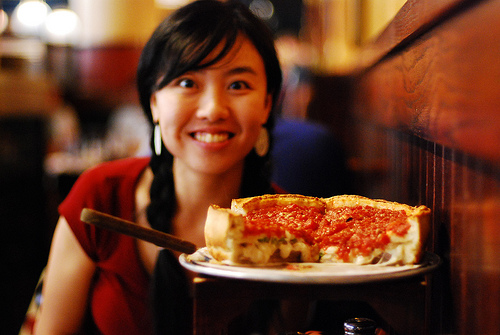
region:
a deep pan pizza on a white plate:
[180, 193, 430, 276]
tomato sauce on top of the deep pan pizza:
[243, 206, 412, 261]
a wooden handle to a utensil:
[80, 208, 197, 254]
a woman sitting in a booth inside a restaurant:
[32, 0, 444, 333]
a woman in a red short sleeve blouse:
[3, 1, 495, 333]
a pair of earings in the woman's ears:
[151, 123, 269, 161]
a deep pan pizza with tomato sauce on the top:
[177, 189, 432, 284]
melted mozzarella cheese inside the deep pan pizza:
[240, 242, 306, 263]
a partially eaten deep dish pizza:
[176, 190, 441, 281]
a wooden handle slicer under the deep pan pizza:
[79, 205, 209, 262]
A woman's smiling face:
[138, 3, 278, 168]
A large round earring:
[254, 120, 271, 157]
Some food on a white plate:
[196, 191, 428, 278]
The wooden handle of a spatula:
[80, 205, 197, 265]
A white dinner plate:
[181, 245, 439, 285]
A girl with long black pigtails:
[139, 0, 276, 327]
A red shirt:
[58, 161, 294, 331]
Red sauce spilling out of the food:
[255, 202, 380, 242]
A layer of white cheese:
[238, 232, 404, 266]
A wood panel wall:
[336, 1, 499, 330]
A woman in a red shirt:
[31, 5, 288, 334]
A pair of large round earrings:
[148, 126, 273, 156]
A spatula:
[83, 210, 284, 267]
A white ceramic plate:
[178, 248, 430, 280]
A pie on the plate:
[203, 193, 434, 268]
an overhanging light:
[11, 0, 54, 35]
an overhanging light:
[38, 6, 82, 47]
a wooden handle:
[82, 208, 197, 256]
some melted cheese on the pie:
[243, 239, 401, 269]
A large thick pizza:
[204, 192, 430, 264]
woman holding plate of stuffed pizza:
[41, 5, 444, 330]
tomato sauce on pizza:
[247, 204, 344, 231]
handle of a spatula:
[72, 198, 192, 257]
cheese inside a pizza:
[249, 241, 323, 265]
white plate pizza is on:
[202, 262, 393, 292]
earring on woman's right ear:
[147, 122, 174, 157]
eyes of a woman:
[163, 59, 262, 103]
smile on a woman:
[181, 123, 242, 157]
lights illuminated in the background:
[9, 0, 89, 52]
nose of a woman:
[189, 98, 237, 126]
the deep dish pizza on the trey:
[196, 190, 424, 272]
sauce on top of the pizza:
[246, 206, 402, 246]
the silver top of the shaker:
[334, 309, 383, 332]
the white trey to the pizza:
[183, 256, 430, 278]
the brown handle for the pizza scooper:
[77, 206, 196, 257]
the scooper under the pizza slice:
[77, 204, 319, 271]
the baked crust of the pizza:
[237, 189, 371, 206]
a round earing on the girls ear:
[257, 124, 268, 158]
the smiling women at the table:
[140, 13, 284, 178]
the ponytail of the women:
[139, 146, 191, 334]